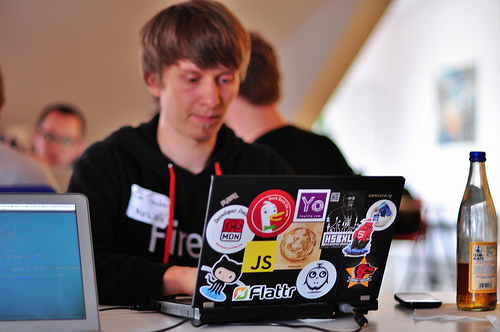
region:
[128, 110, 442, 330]
a black laptop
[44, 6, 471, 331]
a man on a laptop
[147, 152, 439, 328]
a laptop with stickers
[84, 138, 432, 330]
a laptop with a lot of stickers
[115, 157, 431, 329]
black laptop with stickers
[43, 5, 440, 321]
guy typing on laptop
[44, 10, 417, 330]
guy looking at laptop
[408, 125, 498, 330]
a bottle drink on table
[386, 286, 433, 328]
cell phone laying on table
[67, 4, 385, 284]
man wearing black hoodie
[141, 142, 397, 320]
Computer on a table.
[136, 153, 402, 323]
Computer is a laptop.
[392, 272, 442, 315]
Phone on the table.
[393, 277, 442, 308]
The phone is black.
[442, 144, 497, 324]
Bottle on the table.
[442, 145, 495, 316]
the bottle is glass.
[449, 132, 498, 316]
The bottle is half full.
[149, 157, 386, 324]
The laptop has stickers.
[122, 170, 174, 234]
The name tag is white.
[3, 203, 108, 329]
The monitor is silver.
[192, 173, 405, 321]
the back of a laptop screen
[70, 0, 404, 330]
a young man using a laptop computer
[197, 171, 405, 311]
stickers on the back of the laptop screen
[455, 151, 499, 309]
a soda bottle on top of the table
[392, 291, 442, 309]
a cell phone on top of the desk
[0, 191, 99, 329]
a laptop screen across from the young man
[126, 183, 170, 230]
a name tag on the boys shirt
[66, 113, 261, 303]
the young man is wearing a black shirt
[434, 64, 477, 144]
a picture is hanging on the wall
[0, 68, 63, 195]
a man sitting at the table behind the young man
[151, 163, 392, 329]
The laptop is black.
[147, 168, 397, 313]
Laptop covered in stickers.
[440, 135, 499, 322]
Drink is half gone.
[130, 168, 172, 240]
Name tag is white.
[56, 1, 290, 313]
The user is male.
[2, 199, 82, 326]
The screen is blue.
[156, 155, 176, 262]
Hoodie strings are red.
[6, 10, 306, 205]
People in the background.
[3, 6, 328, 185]
People in back are blurry.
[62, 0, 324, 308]
Young man sitting at a table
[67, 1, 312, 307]
Young man on a laptop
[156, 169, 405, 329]
Black laptop on a table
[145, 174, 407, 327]
Laptop with lots of stickers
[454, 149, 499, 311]
Glass drink on a table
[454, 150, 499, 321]
Glass bottle with a blue twist top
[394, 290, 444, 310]
Cell phone on a table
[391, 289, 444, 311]
Cell phone sitting face up on a table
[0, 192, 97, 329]
A silver laptop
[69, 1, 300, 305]
A young man wearing a black hoodie